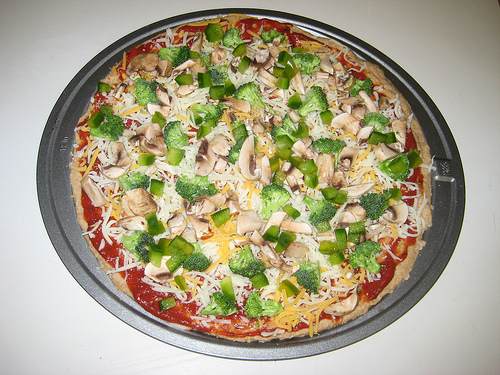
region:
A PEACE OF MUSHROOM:
[79, 161, 112, 208]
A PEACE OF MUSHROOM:
[126, 183, 155, 218]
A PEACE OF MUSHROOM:
[112, 141, 130, 176]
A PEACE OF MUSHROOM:
[163, 212, 195, 232]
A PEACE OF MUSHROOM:
[263, 200, 295, 229]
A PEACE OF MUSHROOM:
[343, 202, 365, 227]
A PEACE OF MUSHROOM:
[237, 139, 260, 179]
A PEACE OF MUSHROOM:
[388, 124, 403, 145]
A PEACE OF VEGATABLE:
[163, 124, 183, 151]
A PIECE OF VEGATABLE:
[172, 177, 222, 207]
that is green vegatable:
[171, 119, 185, 156]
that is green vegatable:
[289, 260, 318, 291]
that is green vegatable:
[351, 229, 389, 271]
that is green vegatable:
[386, 150, 413, 184]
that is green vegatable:
[184, 246, 203, 276]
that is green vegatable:
[163, 119, 180, 150]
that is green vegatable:
[97, 109, 117, 142]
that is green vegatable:
[133, 83, 159, 101]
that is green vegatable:
[161, 42, 185, 67]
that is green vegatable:
[206, 25, 219, 45]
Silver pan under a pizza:
[33, 8, 466, 363]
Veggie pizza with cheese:
[68, 12, 431, 342]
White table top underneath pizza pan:
[0, 1, 498, 373]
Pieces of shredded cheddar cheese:
[274, 313, 301, 333]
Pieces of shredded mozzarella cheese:
[406, 191, 429, 238]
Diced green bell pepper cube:
[164, 146, 186, 165]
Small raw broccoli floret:
[260, 184, 291, 211]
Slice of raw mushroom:
[236, 134, 263, 181]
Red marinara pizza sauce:
[135, 286, 156, 307]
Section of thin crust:
[412, 120, 434, 162]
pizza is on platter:
[67, 21, 418, 348]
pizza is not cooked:
[77, 3, 398, 340]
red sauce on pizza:
[74, 15, 412, 325]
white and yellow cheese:
[95, 21, 405, 319]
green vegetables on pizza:
[100, 13, 410, 331]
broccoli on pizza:
[111, 40, 398, 284]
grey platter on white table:
[100, 40, 412, 322]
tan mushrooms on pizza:
[92, 54, 427, 372]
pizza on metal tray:
[82, 27, 462, 341]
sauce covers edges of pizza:
[55, 70, 400, 357]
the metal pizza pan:
[36, 7, 466, 361]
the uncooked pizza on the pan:
[68, 12, 442, 341]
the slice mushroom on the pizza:
[239, 135, 259, 178]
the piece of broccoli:
[228, 245, 263, 277]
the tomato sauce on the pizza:
[69, 14, 436, 341]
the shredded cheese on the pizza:
[71, 11, 433, 341]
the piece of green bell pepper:
[210, 208, 230, 228]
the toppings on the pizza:
[69, 13, 434, 341]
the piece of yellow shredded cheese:
[82, 148, 99, 178]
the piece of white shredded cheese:
[427, 153, 434, 173]